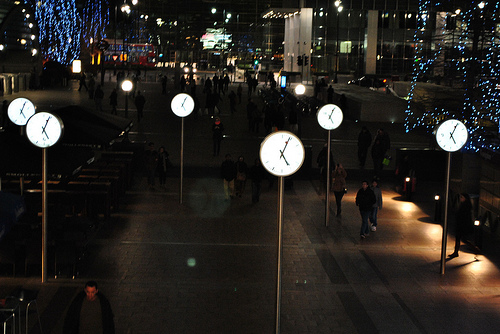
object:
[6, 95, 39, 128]
clocks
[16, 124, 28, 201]
pole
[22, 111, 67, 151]
clocks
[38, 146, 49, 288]
pole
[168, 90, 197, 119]
clocks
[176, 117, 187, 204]
pole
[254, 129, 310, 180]
clocks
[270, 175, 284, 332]
pole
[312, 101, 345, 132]
clocks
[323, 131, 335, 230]
pole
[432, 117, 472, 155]
clocks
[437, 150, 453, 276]
pole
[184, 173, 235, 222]
reflection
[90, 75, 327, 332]
pathway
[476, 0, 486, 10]
lights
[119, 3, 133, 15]
lights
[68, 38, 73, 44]
lights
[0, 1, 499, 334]
picture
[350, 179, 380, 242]
people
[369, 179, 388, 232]
people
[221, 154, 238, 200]
people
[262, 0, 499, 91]
buildings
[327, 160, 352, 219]
people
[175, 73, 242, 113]
crowd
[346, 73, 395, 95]
car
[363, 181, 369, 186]
hair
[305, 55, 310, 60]
lights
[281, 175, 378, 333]
edge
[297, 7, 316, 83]
columns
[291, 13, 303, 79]
columns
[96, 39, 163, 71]
bus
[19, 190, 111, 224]
table